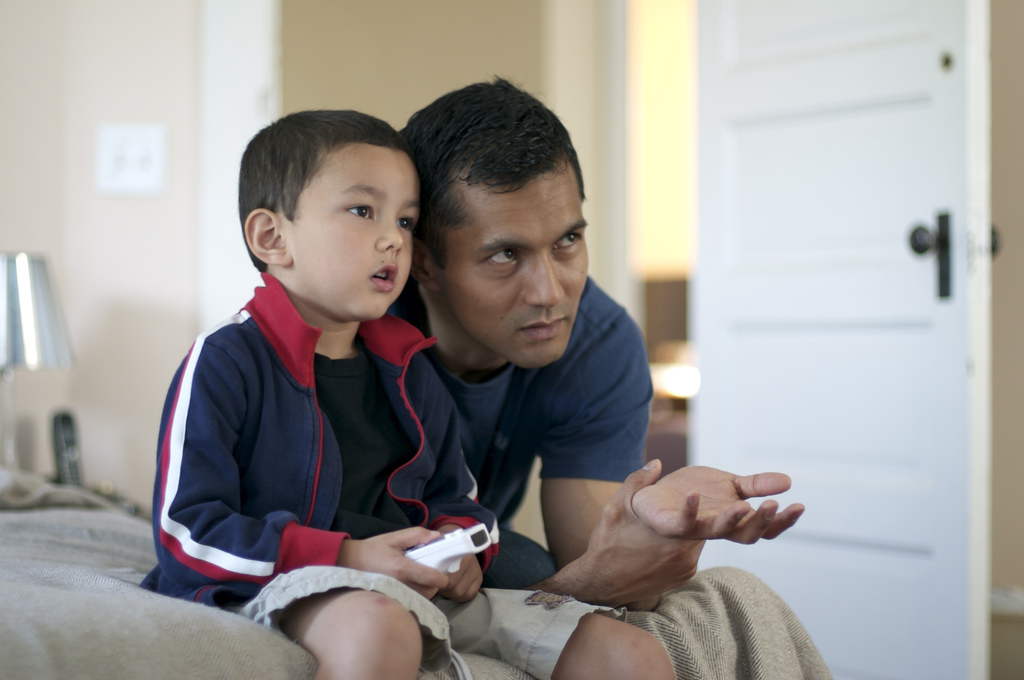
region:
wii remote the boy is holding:
[380, 516, 565, 633]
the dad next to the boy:
[378, 72, 812, 600]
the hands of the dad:
[579, 449, 837, 605]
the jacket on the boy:
[115, 271, 548, 585]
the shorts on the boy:
[229, 537, 613, 675]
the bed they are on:
[4, 454, 890, 674]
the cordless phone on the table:
[32, 391, 128, 522]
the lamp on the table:
[1, 243, 110, 490]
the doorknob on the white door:
[909, 209, 976, 312]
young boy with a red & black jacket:
[147, 97, 457, 677]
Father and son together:
[148, 92, 698, 397]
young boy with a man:
[182, 73, 717, 671]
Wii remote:
[337, 502, 562, 616]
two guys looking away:
[106, 69, 830, 668]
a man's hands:
[546, 455, 838, 633]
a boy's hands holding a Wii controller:
[285, 496, 533, 623]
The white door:
[675, 4, 990, 668]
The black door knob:
[900, 202, 961, 292]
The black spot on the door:
[930, 39, 957, 81]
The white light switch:
[72, 114, 175, 190]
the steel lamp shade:
[5, 244, 86, 366]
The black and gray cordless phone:
[43, 406, 88, 482]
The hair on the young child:
[220, 107, 417, 276]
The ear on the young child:
[246, 200, 300, 278]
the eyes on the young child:
[337, 202, 421, 234]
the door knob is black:
[909, 212, 949, 296]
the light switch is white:
[92, 120, 168, 193]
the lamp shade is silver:
[0, 250, 71, 372]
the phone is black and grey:
[48, 410, 86, 487]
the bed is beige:
[2, 465, 825, 672]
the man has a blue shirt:
[399, 73, 805, 595]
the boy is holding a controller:
[146, 102, 675, 676]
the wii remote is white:
[406, 522, 486, 573]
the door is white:
[689, 0, 994, 675]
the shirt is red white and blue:
[136, 272, 501, 602]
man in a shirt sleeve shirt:
[416, 78, 808, 582]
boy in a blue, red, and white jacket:
[141, 104, 421, 674]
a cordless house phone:
[46, 405, 86, 485]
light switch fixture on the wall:
[93, 119, 170, 197]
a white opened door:
[696, 0, 987, 669]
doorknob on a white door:
[904, 209, 984, 302]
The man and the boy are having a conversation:
[160, 54, 692, 558]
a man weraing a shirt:
[529, 146, 667, 608]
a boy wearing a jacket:
[204, 257, 511, 640]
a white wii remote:
[391, 499, 565, 623]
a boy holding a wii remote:
[267, 391, 588, 655]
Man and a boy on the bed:
[3, 70, 839, 677]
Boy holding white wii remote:
[147, 107, 683, 677]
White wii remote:
[405, 519, 494, 574]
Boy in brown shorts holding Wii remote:
[141, 107, 679, 677]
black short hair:
[395, 75, 588, 272]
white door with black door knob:
[685, 2, 998, 677]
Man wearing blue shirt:
[376, 72, 809, 616]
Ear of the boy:
[242, 203, 296, 268]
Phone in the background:
[47, 404, 85, 484]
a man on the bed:
[428, 63, 806, 580]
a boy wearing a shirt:
[258, 271, 549, 633]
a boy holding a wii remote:
[236, 256, 562, 677]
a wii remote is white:
[397, 486, 506, 600]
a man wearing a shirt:
[406, 99, 669, 586]